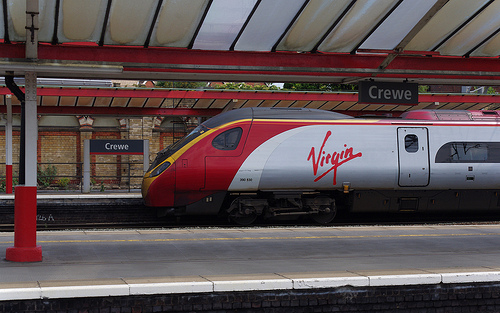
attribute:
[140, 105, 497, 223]
train — gray, black, virgin, part, branding, silver, red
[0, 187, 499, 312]
platform — floor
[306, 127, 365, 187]
logo — graphic, virgin, red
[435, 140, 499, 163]
window — side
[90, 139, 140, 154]
sign — black, informational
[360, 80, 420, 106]
sign — black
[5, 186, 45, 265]
pylon — red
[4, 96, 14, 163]
beam — metal